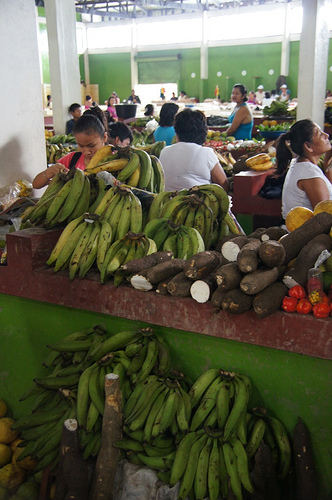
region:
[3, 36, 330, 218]
People in a market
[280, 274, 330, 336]
Red peppers on a table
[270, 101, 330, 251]
A woman wearing a white shirt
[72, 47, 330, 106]
A green wall in the distance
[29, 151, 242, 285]
A bunch of green bananas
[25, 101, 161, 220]
A woman looking at bananas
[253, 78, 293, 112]
Two people wearing white hats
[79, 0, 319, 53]
Sun shining through the windows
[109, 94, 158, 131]
A black bucket on top of the table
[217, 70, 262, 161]
A woman in a turquoise tank top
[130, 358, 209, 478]
the bananas are green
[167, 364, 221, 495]
the bananas are green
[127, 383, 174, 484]
the bananas are green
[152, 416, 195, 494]
the bananas are green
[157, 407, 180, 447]
the bananas are green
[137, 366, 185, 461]
the bananas are green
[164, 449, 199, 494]
the bananas are green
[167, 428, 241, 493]
bunch of green bananas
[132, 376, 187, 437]
bunch of green bananas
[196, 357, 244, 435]
bunch of green bananas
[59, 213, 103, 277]
bunch of green bananas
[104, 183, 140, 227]
bunch of green bananas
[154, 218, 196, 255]
bunch of green bananas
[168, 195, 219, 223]
bunch of green bananas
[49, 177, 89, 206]
bunch of green bananas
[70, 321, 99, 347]
bunch of green bananas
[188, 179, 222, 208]
bunch of green bananas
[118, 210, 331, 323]
pile of brown and white casava roots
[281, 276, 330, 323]
pile of red bell peppers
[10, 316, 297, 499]
stack of green plantains leaning against a green wall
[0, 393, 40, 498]
pile of yellow melons leaning against a green wall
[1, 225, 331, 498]
a green wall with a red brick top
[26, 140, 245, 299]
stack of green and yellow ripening plantains sitting on a brick wall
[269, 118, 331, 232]
woman with a pony tail wearing a white shirt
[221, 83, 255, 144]
woman wearing a blue sleeveless shirt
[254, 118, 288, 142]
blue bowl holding fruit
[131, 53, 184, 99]
partially opened green garage door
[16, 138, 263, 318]
bananas out on display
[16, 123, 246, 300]
bananas on a table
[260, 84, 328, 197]
a woman with a pony tail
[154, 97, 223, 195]
a woman with a white shirt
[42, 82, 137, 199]
a woman wearing a pink shirt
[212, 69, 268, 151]
a woman wearing a blue tank top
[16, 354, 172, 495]
two sticks of wood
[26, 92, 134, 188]
a woman wearing a bracelet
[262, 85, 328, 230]
a woman wearing a white tank top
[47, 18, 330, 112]
green walls